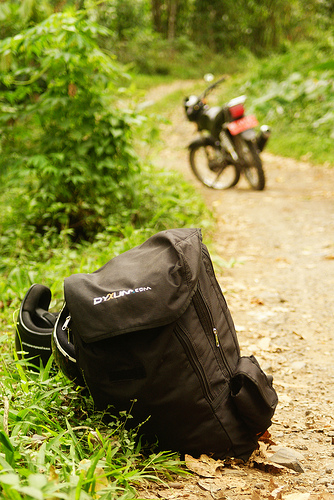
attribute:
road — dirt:
[252, 198, 300, 229]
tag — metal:
[212, 328, 219, 347]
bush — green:
[0, 12, 194, 260]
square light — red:
[229, 97, 252, 124]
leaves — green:
[2, 1, 331, 439]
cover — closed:
[63, 227, 202, 339]